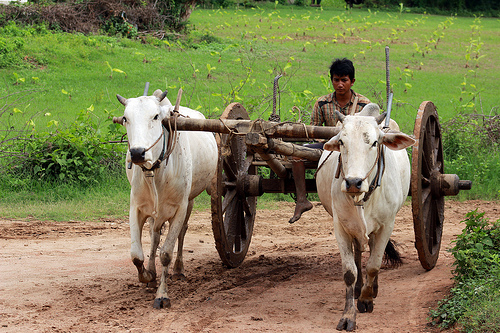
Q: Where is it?
A: This is at the field.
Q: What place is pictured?
A: It is a field.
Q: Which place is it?
A: It is a field.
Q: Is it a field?
A: Yes, it is a field.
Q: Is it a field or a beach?
A: It is a field.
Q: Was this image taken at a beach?
A: No, the picture was taken in a field.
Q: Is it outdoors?
A: Yes, it is outdoors.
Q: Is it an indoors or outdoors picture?
A: It is outdoors.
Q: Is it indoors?
A: No, it is outdoors.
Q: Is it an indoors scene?
A: No, it is outdoors.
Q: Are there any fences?
A: No, there are no fences.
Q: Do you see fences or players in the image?
A: No, there are no fences or players.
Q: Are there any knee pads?
A: No, there are no knee pads.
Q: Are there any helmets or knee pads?
A: No, there are no knee pads or helmets.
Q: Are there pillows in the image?
A: No, there are no pillows.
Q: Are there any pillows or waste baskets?
A: No, there are no pillows or waste baskets.